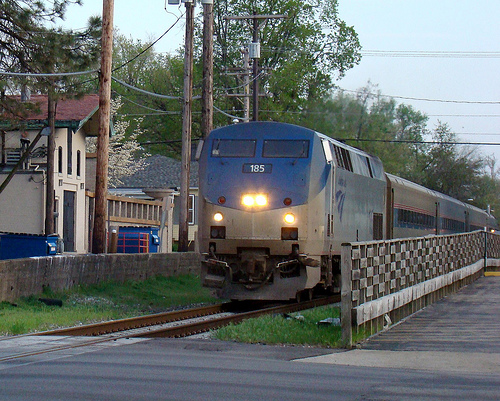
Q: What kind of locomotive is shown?
A: Train.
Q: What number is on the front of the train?
A: 185.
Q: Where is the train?
A: On the train tracks.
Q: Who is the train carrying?
A: Passengers.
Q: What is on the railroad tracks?
A: Train.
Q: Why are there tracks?
A: For train to travel.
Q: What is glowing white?
A: Train lights.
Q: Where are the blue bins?
A: Left of wall.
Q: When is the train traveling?
A: Clear day.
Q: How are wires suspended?
A: Telephone poles.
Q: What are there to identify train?
A: Numbers on front.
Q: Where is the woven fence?
A: Right of train.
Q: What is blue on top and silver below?
A: Train.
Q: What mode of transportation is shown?
A: Train.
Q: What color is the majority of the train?
A: Blue.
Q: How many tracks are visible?
A: Two.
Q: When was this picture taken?
A: Day time.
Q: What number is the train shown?
A: 185.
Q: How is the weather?
A: Clear.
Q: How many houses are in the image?
A: Two.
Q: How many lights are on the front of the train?
A: Four.